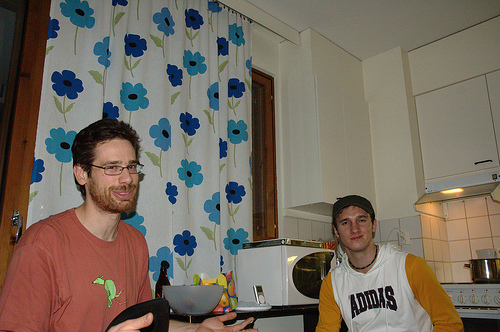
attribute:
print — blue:
[121, 32, 147, 74]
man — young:
[312, 194, 469, 329]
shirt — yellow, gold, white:
[319, 247, 462, 331]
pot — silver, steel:
[466, 257, 499, 281]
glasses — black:
[80, 158, 142, 176]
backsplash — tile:
[375, 203, 500, 281]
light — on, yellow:
[441, 186, 465, 196]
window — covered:
[251, 69, 280, 242]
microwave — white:
[235, 247, 335, 303]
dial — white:
[460, 292, 468, 303]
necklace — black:
[345, 246, 377, 269]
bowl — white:
[161, 284, 222, 315]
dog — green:
[92, 277, 123, 306]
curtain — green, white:
[29, 3, 254, 277]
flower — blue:
[50, 71, 82, 119]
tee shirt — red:
[1, 206, 152, 330]